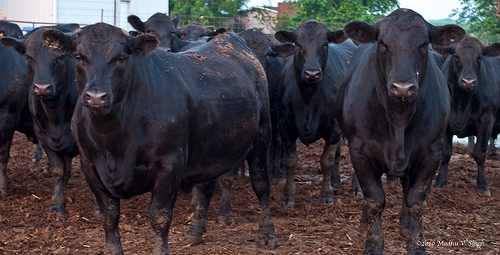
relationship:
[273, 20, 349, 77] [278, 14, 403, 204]
face of a cow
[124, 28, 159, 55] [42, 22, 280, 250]
ear of a cow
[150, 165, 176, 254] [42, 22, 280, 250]
front leg of a cow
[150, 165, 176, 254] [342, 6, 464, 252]
front leg of a cow is black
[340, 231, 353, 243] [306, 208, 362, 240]
wooden chip on soil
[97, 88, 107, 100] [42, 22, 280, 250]
nostril of a cow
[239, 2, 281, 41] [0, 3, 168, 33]
building next to cowshed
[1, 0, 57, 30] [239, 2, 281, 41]
door of building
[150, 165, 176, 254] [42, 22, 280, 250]
front leg of cow